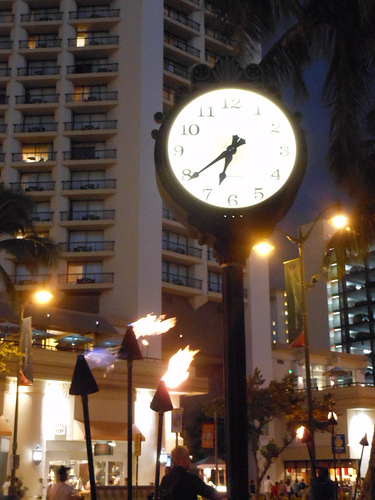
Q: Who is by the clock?
A: A man.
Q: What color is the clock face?
A: White.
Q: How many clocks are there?
A: One.